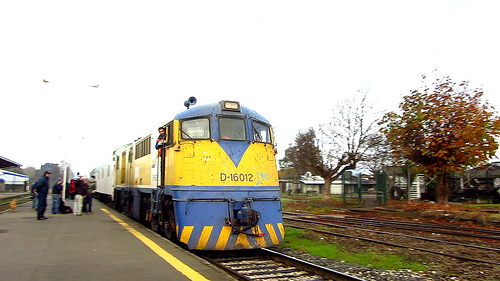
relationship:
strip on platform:
[91, 195, 196, 278] [0, 131, 213, 279]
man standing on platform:
[86, 175, 97, 213] [5, 182, 228, 278]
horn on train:
[173, 82, 209, 115] [82, 64, 285, 266]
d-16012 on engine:
[220, 173, 253, 182] [97, 78, 307, 252]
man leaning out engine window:
[143, 115, 181, 180] [181, 117, 211, 139]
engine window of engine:
[181, 117, 211, 139] [86, 83, 315, 264]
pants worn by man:
[65, 189, 83, 219] [47, 160, 96, 216]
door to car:
[111, 142, 129, 194] [82, 103, 329, 273]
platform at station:
[5, 182, 228, 278] [0, 149, 237, 247]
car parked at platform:
[90, 96, 286, 250] [0, 193, 240, 281]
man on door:
[154, 127, 166, 158] [148, 113, 178, 189]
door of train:
[148, 113, 178, 189] [80, 56, 293, 276]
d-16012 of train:
[220, 173, 253, 182] [82, 85, 292, 277]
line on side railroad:
[89, 192, 213, 279] [137, 183, 329, 277]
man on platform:
[30, 171, 52, 220] [2, 148, 246, 278]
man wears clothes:
[30, 171, 52, 220] [27, 158, 57, 214]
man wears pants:
[72, 175, 85, 215] [68, 183, 86, 215]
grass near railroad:
[282, 214, 448, 277] [207, 199, 387, 279]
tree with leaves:
[378, 67, 492, 208] [378, 65, 489, 162]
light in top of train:
[216, 90, 246, 116] [56, 86, 305, 276]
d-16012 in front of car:
[220, 173, 253, 182] [90, 96, 286, 250]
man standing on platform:
[72, 175, 85, 215] [4, 197, 234, 278]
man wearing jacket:
[32, 170, 52, 220] [32, 176, 49, 191]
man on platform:
[32, 170, 52, 220] [4, 197, 234, 278]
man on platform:
[72, 176, 82, 214] [4, 197, 234, 278]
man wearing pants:
[72, 176, 82, 214] [75, 193, 81, 213]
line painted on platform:
[124, 227, 211, 281] [4, 197, 234, 278]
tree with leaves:
[372, 73, 498, 204] [377, 76, 498, 170]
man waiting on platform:
[72, 175, 85, 215] [0, 193, 240, 281]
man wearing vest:
[154, 127, 166, 158] [158, 135, 163, 153]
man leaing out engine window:
[154, 127, 166, 158] [158, 121, 168, 187]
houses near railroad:
[277, 161, 498, 202] [285, 217, 500, 266]